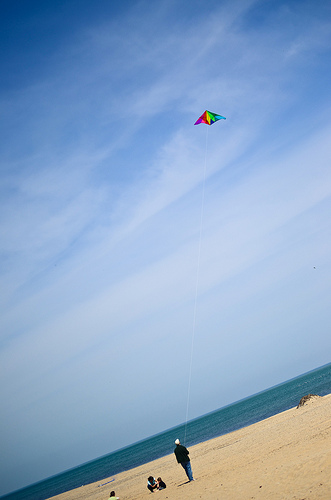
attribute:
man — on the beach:
[173, 439, 195, 483]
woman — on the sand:
[124, 477, 173, 495]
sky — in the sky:
[0, 0, 329, 493]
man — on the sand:
[171, 432, 197, 485]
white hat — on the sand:
[174, 438, 180, 443]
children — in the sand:
[145, 475, 169, 493]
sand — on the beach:
[39, 391, 328, 498]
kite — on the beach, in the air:
[191, 108, 227, 127]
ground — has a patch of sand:
[230, 62, 249, 76]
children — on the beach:
[143, 475, 167, 492]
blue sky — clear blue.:
[2, 1, 329, 498]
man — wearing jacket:
[173, 434, 197, 481]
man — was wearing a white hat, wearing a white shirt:
[169, 436, 197, 482]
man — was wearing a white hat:
[168, 445, 196, 482]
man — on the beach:
[173, 437, 198, 478]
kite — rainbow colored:
[193, 106, 227, 130]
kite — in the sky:
[193, 110, 225, 124]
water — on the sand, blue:
[0, 362, 328, 498]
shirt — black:
[170, 445, 203, 470]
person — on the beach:
[106, 487, 123, 499]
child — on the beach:
[156, 476, 165, 489]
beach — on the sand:
[43, 392, 330, 497]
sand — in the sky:
[68, 392, 324, 496]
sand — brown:
[8, 392, 330, 495]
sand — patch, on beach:
[135, 423, 329, 499]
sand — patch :
[259, 465, 299, 489]